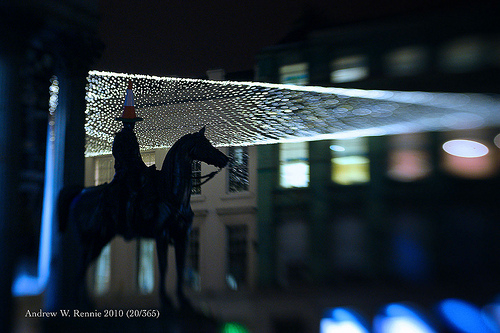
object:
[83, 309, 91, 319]
white letter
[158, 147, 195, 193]
neck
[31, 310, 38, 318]
letter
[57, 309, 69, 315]
letter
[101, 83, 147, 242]
figure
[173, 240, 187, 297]
leg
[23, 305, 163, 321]
tag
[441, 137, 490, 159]
light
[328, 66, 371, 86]
light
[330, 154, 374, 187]
light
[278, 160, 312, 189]
light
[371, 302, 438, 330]
light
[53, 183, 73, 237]
tail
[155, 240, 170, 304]
leg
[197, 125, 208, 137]
ear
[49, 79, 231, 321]
statue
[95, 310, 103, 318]
letter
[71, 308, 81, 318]
letter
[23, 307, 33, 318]
letter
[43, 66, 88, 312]
column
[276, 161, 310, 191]
lights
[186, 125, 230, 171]
head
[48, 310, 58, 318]
letter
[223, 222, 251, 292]
window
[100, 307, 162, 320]
year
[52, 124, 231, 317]
horse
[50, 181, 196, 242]
body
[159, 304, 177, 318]
feet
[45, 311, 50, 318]
letter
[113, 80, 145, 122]
traffic cone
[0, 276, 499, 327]
street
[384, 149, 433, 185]
lights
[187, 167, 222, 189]
reins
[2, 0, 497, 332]
building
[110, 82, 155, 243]
man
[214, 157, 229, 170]
mouth